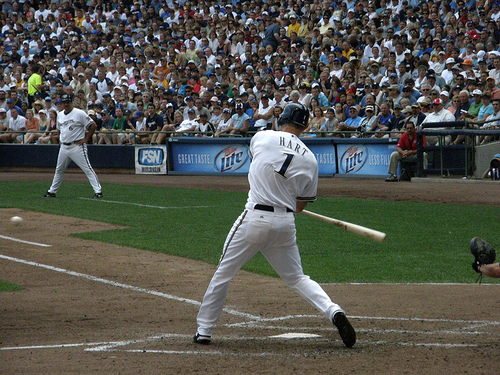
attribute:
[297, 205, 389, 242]
bat — white, long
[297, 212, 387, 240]
bat — wooden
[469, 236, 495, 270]
glove — black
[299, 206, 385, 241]
bat — wooden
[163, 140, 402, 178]
adertisment — miller lite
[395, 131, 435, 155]
shirt — red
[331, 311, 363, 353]
bottom — black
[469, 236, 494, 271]
mitt — black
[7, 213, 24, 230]
ball — white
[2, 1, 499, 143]
crowd — large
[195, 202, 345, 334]
pants — white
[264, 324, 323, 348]
plate base — white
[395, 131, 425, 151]
shirt — red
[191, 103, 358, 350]
player — at bat